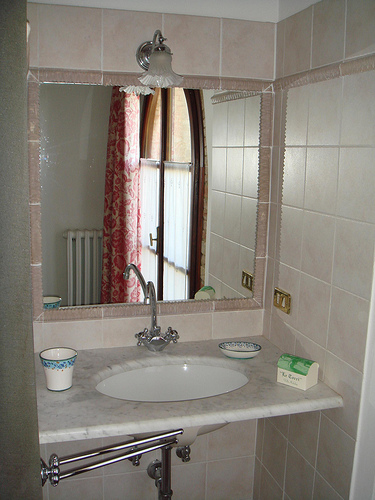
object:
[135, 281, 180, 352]
faucet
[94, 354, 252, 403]
sink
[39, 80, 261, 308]
mirror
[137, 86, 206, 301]
arched window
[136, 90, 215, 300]
brown frame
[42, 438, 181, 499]
silver piping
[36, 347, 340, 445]
countertop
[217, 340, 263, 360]
bowl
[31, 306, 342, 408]
vanity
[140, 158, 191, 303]
curtain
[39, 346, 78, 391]
cup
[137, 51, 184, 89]
lamp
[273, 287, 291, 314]
lights.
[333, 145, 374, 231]
tile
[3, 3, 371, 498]
bathroom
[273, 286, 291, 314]
gold outlet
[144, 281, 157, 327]
spout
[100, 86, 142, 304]
curtain